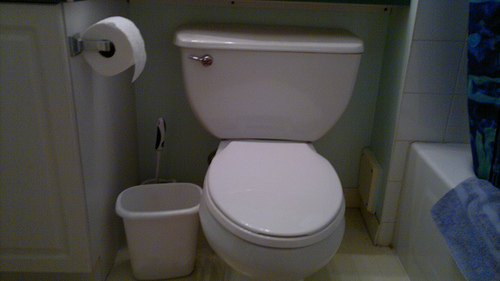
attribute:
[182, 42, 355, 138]
tank — white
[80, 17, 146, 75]
roll — white, toilet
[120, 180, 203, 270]
bin — white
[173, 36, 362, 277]
toilet — white, bathroom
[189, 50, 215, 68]
handle — silver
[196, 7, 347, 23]
wall — green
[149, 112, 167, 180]
brush — blue, white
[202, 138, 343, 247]
seat — down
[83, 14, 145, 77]
paper — roll, toilet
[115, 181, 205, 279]
can — white, trash, plastic, garbage, small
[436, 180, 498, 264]
towel — blue, hanging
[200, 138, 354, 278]
bowl — white, toilet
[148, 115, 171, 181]
handle — toilet, brush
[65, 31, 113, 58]
holder — silver, toilet, paper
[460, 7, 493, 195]
curtain — shower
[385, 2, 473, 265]
wall — white, tile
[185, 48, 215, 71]
handle — silver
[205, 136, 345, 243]
lid — down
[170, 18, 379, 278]
commode — white, porcelain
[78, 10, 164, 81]
roll — toilet paper, hung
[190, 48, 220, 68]
handle — toilet, flush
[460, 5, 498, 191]
curtain — shower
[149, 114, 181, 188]
brush — toilet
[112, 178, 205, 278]
wastebasket — bathroom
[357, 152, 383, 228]
access — plumbing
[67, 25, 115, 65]
bracket — toilet paper, holder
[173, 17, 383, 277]
bowl — white, toilet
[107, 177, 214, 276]
can — small, white, trash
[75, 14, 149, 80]
paper — roll, toilet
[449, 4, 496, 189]
curtain — colorful, shower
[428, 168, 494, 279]
towel — folded, blue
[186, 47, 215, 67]
handle — silver, flush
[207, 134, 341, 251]
cover — white, toilet seat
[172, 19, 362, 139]
tank — toilet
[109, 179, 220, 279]
bin — trash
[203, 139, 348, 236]
lid — down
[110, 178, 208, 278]
garbage can — empty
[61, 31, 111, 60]
dispensor — metal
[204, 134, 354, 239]
seat — down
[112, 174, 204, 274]
trash can — white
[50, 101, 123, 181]
building — side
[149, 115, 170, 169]
brush — toilet, bowl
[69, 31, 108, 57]
holder — toilet, paper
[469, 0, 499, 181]
curtain — shower